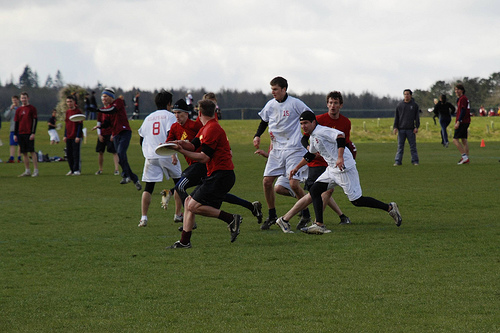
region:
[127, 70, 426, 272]
group of people playing frisbee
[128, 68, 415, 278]
two frisbee teams in action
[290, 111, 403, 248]
man in white uniform running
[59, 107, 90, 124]
white frisbee in air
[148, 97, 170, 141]
the number eight on a white shirt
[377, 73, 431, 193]
man in dark clothing standing in grass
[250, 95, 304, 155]
white uniform shirt with red logo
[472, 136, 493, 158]
orange boundry cone on field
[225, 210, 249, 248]
black Nike shoe with spikes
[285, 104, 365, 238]
man in white uniform with black elbow pads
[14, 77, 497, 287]
a big group of people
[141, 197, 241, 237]
leg of the person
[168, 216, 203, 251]
shoe of the person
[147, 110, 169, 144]
number of the person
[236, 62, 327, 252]
tallest boy in the group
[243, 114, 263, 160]
hand of the person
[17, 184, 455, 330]
a beautiful view of green ground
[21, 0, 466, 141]
a cool looking sky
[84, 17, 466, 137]
beautiful view of clouds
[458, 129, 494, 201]
a small red object in ground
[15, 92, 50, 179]
this is a person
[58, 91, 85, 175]
this is a person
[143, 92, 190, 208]
this is a person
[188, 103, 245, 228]
this is a person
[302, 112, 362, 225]
this is a person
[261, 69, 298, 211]
this is a person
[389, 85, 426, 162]
this is a person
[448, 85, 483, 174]
this is a person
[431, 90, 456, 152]
this is a person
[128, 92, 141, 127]
this is a person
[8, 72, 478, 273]
both teams have white and red uniform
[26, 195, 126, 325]
the grass is well manicured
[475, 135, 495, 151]
the cone is orange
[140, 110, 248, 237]
he is holding a frisbbe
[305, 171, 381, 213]
the socks are black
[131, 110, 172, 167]
number 8 is on the shirt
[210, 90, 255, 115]
trees are in the background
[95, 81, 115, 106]
the marvin is blue ,white and black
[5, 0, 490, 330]
the sun is setting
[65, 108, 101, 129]
the frisbee is in the air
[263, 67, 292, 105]
Man has brown hair.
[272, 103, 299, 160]
Man is wearing white shirt.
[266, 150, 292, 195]
Man is wearing white shorts.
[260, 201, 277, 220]
Man is wearing black socks.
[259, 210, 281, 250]
Man is wearing black shoes.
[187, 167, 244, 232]
Man is wearing black shorts.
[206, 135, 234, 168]
Man is wearing red shirt.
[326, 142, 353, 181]
Man is wearing white shirt.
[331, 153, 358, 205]
Man is wearing white shorts.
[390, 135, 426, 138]
Person is wearing blue jeans.